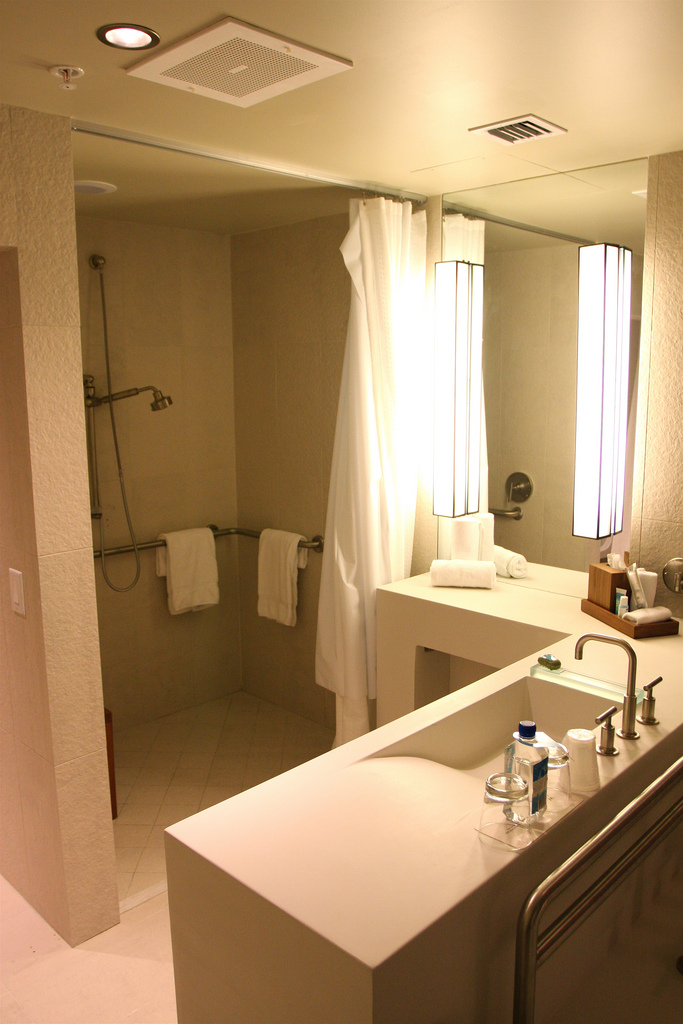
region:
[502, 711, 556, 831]
The bottle of Fiji water on the counter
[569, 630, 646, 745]
The faucet of the sink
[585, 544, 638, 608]
The wooden cover for the kleenex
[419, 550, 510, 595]
The rolled up towel laying on the counter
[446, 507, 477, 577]
The rolled up towel that is standing up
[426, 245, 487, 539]
The light sconce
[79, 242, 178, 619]
The shower head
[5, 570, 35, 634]
The light switch on the wall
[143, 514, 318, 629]
The towels hanging in the shower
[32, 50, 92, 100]
The sprinkler on the ceiling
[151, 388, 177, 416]
The silver shower head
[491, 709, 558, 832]
The bottle of water on the sink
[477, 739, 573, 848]
The glasses next to the water bottle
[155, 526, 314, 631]
The two towels hanging in the shower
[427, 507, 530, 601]
The rolled up towels on the counter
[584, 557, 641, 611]
The brown wood tissue box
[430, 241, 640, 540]
The lights on the mirror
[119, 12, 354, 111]
The rectangular speaker in the ceiling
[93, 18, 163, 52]
The light next to the speaker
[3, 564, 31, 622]
The light switch on the wall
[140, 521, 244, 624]
white towel hanging in bathroom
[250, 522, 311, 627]
white towel hanging in bathroom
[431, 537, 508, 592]
white towel rolled up in bathroom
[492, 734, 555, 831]
soap bottle in bathroom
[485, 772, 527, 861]
clear glass in bathroom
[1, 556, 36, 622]
white light switch in bathroom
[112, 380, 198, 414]
shower faucet in bathroom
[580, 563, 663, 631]
brown tray in bathroom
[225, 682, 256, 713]
a tile in a floor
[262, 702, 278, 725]
a tile in a floor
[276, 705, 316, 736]
a tile in a floor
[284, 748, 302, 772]
a tile in a floor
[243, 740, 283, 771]
a tile in a floor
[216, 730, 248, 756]
a tile in a floor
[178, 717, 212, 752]
a tile in a floor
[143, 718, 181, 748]
a tile in a floor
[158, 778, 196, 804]
a tile in a floor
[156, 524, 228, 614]
white towel in the bathroom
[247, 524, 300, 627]
white towel in the bathroom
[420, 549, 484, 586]
white towel in the bathroom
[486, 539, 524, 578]
white towel in the bathroom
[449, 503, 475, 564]
white towel in the bathroom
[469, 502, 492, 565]
white towel in the bathroom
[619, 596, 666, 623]
white towel in the bathroom